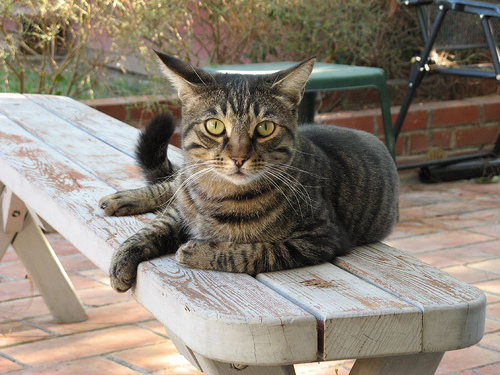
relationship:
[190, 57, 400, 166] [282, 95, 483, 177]
table by wall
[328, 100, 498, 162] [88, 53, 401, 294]
wall behind cat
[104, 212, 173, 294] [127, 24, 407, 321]
leg on a cat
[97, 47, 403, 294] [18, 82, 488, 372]
cat on top of bench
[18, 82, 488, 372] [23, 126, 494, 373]
bench on top of patio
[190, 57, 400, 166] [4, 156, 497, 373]
table on top of patio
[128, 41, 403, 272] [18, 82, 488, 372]
cat on top of bench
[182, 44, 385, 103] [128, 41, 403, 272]
table behind cat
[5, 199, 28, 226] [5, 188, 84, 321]
bolt attached to legs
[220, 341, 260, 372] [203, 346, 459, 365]
bolt attached to legs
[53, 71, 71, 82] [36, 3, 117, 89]
leaf on a stem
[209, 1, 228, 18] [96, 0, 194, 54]
leaf on a stem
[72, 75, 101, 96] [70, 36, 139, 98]
leaf on a stem